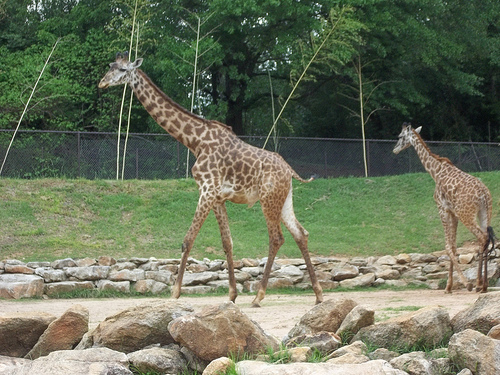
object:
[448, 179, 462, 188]
spot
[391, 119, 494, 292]
baby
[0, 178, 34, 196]
grass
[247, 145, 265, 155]
spot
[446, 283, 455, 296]
hoof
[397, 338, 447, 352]
grass growth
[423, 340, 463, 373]
grass growth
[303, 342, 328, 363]
grass growth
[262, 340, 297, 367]
grass growth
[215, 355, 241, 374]
grass growth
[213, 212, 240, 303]
leg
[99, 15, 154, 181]
tree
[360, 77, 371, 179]
thin trunk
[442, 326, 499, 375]
rock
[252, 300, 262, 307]
hoof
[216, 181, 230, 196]
brown spot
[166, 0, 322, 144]
tree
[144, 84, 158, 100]
spot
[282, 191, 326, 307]
leg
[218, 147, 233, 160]
brown spot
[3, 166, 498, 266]
slope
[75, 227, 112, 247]
grass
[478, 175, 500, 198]
green grass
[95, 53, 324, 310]
giraffe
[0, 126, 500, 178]
fence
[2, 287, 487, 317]
path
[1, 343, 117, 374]
rocks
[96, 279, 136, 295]
stones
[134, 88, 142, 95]
spot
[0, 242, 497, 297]
rock wall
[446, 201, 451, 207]
spots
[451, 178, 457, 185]
spots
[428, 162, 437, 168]
spots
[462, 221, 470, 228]
spots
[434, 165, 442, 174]
spots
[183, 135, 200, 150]
spot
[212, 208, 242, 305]
leg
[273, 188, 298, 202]
spot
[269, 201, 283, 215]
spot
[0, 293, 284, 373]
boulders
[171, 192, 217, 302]
leg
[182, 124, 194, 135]
spot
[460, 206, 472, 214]
spot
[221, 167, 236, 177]
brown spot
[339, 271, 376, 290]
stone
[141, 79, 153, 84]
spot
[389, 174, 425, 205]
grass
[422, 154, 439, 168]
spot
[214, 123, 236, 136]
spot